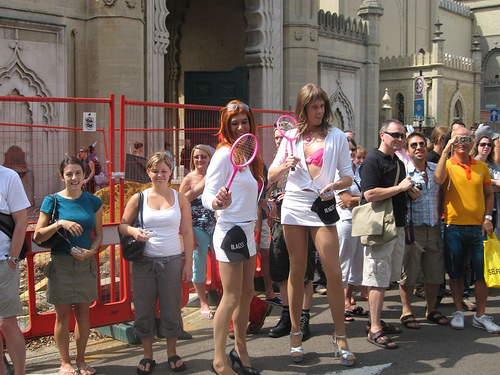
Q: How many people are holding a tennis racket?
A: Two.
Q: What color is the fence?
A: Red.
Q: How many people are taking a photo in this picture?
A: One.